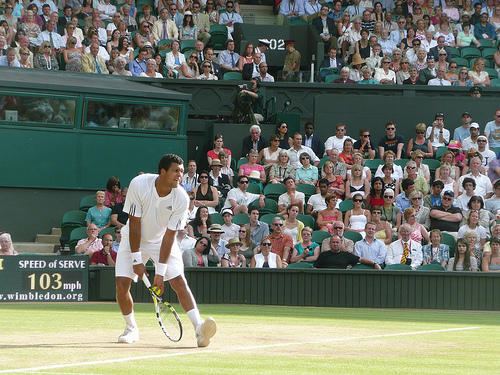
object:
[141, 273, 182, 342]
racket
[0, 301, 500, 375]
court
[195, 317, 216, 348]
shoe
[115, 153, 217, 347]
man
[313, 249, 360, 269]
shirt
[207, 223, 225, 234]
cap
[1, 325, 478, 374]
line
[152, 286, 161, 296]
ball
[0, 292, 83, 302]
address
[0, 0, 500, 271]
seating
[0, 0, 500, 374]
match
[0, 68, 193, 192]
stadium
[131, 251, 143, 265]
wristband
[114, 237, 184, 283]
short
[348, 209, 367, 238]
vest